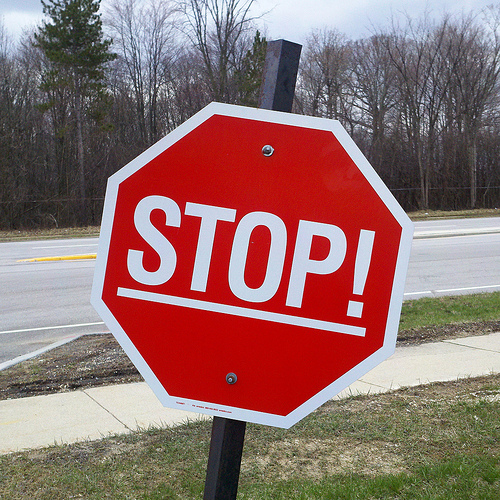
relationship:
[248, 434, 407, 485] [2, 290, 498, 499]
sand in grass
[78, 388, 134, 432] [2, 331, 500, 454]
groove in sidewalk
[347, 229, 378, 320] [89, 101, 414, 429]
exclamation mark on a border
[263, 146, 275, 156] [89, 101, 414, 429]
screw on a border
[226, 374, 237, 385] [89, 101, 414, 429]
screw on a border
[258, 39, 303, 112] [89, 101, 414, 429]
post holding border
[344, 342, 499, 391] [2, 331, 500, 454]
section of sidewalk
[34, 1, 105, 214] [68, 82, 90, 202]
tree has trunk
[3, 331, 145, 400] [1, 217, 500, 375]
dirt near street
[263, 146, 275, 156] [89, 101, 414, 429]
screw holding border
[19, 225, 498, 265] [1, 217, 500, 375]
line in road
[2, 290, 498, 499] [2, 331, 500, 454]
grass near sidewalk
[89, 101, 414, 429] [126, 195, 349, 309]
border says stop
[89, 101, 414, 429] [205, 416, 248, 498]
border on a pole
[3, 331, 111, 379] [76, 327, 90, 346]
curb has a point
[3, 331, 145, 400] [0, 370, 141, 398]
dirt has tracks